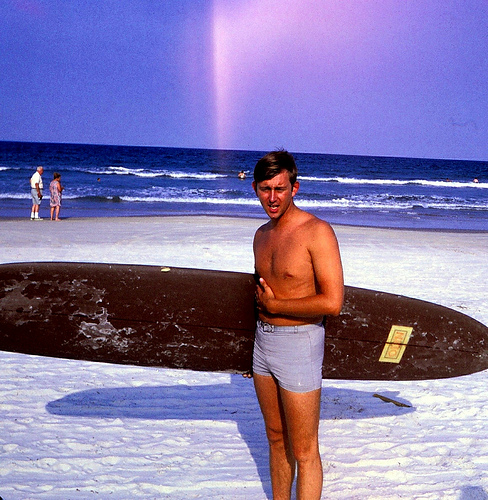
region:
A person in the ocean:
[235, 166, 248, 179]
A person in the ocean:
[443, 176, 452, 184]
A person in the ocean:
[471, 176, 481, 185]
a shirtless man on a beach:
[240, 146, 349, 498]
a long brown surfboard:
[1, 260, 487, 383]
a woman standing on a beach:
[46, 171, 65, 221]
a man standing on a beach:
[27, 163, 45, 219]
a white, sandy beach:
[2, 218, 481, 498]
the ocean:
[1, 139, 486, 217]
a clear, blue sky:
[0, 0, 487, 160]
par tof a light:
[232, 27, 275, 61]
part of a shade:
[377, 375, 414, 404]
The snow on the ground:
[15, 373, 229, 478]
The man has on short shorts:
[244, 311, 332, 398]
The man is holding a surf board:
[2, 135, 483, 498]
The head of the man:
[249, 145, 300, 223]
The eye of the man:
[270, 181, 286, 194]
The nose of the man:
[265, 189, 278, 204]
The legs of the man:
[254, 378, 329, 495]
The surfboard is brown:
[31, 267, 219, 352]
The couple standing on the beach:
[21, 161, 73, 227]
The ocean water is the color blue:
[42, 129, 203, 165]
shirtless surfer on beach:
[232, 155, 350, 498]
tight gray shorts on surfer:
[244, 317, 331, 402]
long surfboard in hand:
[18, 258, 448, 405]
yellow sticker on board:
[365, 318, 423, 373]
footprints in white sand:
[91, 366, 255, 492]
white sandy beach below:
[35, 363, 364, 491]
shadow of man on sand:
[80, 364, 296, 476]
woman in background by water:
[46, 169, 61, 225]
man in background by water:
[24, 173, 45, 216]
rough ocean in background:
[36, 140, 484, 204]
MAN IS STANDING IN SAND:
[246, 192, 341, 495]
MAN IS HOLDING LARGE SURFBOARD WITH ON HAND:
[7, 252, 485, 387]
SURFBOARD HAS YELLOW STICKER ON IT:
[376, 319, 420, 368]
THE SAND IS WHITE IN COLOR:
[8, 220, 468, 479]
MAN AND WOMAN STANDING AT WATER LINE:
[27, 163, 66, 226]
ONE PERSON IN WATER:
[230, 166, 250, 187]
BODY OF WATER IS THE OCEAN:
[3, 141, 482, 236]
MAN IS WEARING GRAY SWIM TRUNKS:
[249, 311, 328, 400]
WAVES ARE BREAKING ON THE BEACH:
[104, 191, 484, 222]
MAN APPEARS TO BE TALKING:
[250, 145, 302, 224]